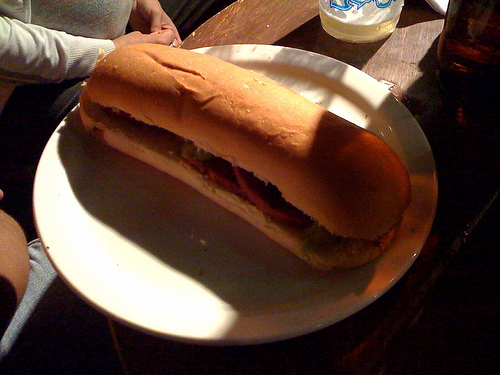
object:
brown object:
[2, 209, 33, 312]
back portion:
[78, 42, 185, 176]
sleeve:
[2, 18, 115, 79]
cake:
[320, 0, 400, 45]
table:
[164, 0, 495, 370]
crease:
[141, 50, 207, 83]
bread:
[78, 42, 412, 273]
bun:
[75, 42, 409, 270]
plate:
[33, 44, 440, 349]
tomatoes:
[167, 137, 305, 227]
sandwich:
[76, 42, 411, 272]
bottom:
[316, 9, 395, 42]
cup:
[317, 0, 403, 44]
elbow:
[0, 194, 28, 336]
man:
[0, 213, 32, 361]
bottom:
[435, 0, 498, 79]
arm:
[0, 15, 116, 84]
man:
[0, 1, 178, 77]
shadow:
[394, 74, 500, 263]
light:
[32, 124, 236, 359]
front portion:
[264, 89, 417, 274]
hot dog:
[88, 95, 344, 257]